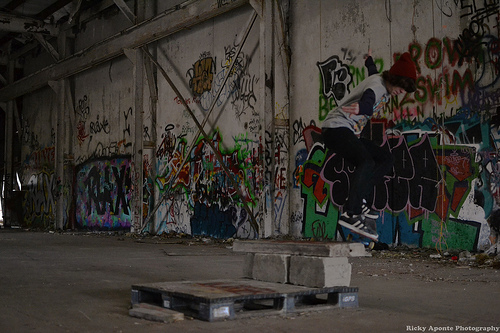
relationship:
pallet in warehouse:
[129, 273, 359, 312] [7, 3, 500, 328]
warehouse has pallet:
[7, 3, 500, 328] [129, 273, 359, 312]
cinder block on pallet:
[246, 254, 354, 290] [129, 273, 359, 312]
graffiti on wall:
[293, 12, 498, 266] [6, 11, 499, 264]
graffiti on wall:
[188, 55, 220, 97] [6, 11, 499, 264]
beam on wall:
[128, 44, 148, 236] [6, 11, 499, 264]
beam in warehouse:
[128, 44, 148, 236] [7, 3, 500, 328]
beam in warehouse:
[48, 78, 73, 233] [7, 3, 500, 328]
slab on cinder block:
[229, 239, 370, 260] [246, 254, 354, 290]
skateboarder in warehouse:
[319, 42, 417, 241] [7, 3, 500, 328]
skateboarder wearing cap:
[319, 42, 417, 241] [392, 53, 422, 80]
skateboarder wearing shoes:
[319, 42, 417, 241] [340, 204, 384, 243]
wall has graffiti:
[0, 0, 500, 271] [75, 155, 134, 229]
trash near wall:
[430, 243, 500, 266] [6, 11, 499, 264]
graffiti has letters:
[293, 12, 498, 266] [319, 125, 443, 209]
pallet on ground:
[129, 273, 359, 312] [2, 230, 499, 333]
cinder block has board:
[246, 254, 354, 290] [229, 239, 370, 260]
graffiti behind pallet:
[293, 12, 498, 266] [129, 273, 359, 312]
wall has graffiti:
[6, 11, 499, 264] [293, 12, 498, 266]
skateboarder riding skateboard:
[319, 42, 417, 241] [339, 231, 376, 252]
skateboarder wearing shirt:
[319, 42, 417, 241] [322, 73, 388, 126]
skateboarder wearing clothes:
[319, 42, 417, 241] [318, 126, 375, 217]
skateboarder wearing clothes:
[319, 42, 417, 241] [322, 70, 388, 216]